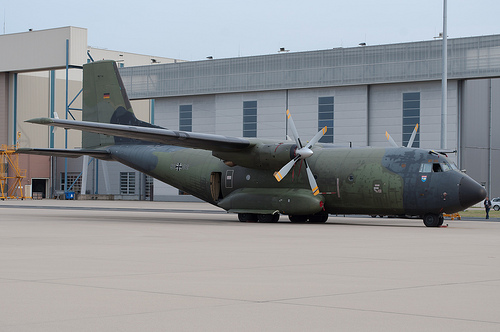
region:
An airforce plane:
[217, 149, 447, 209]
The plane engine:
[264, 142, 289, 159]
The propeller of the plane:
[290, 135, 311, 169]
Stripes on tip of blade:
[313, 189, 318, 194]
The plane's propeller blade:
[310, 176, 313, 183]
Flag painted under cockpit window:
[421, 173, 426, 180]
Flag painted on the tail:
[102, 92, 108, 97]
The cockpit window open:
[433, 162, 439, 169]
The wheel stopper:
[442, 224, 448, 228]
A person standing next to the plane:
[482, 195, 491, 218]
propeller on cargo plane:
[274, 156, 297, 184]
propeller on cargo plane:
[305, 161, 320, 198]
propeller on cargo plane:
[307, 123, 329, 147]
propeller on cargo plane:
[283, 108, 303, 143]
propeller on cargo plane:
[383, 129, 399, 145]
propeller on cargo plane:
[403, 120, 419, 146]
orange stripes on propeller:
[285, 106, 292, 120]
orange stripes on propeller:
[319, 124, 329, 137]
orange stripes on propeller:
[311, 183, 321, 197]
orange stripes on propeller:
[274, 169, 284, 184]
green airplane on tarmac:
[15, 55, 489, 249]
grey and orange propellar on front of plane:
[267, 99, 339, 204]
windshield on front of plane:
[415, 154, 460, 179]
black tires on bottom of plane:
[228, 201, 447, 239]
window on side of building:
[392, 85, 432, 158]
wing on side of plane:
[22, 89, 259, 161]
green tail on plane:
[73, 53, 143, 142]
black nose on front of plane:
[455, 164, 491, 219]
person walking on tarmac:
[478, 186, 496, 221]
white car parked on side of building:
[486, 191, 498, 213]